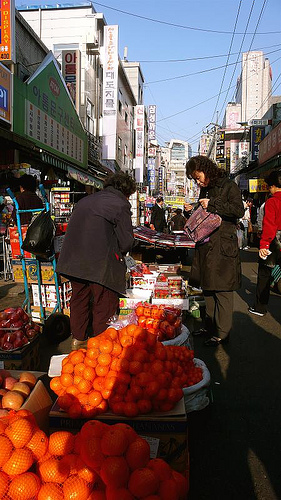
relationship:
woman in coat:
[173, 143, 247, 352] [182, 166, 251, 298]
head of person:
[97, 162, 150, 203] [52, 167, 144, 355]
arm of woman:
[44, 159, 144, 354] [53, 168, 139, 349]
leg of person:
[63, 269, 95, 344] [52, 167, 144, 355]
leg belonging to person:
[90, 282, 118, 336] [54, 170, 138, 350]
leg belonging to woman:
[211, 288, 235, 336] [184, 155, 246, 351]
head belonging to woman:
[185, 154, 213, 187] [184, 155, 246, 351]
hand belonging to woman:
[198, 197, 210, 208] [184, 155, 246, 351]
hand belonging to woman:
[181, 201, 192, 212] [184, 155, 246, 351]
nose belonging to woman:
[195, 178, 200, 184] [184, 155, 246, 351]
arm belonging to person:
[258, 199, 272, 248] [247, 169, 272, 315]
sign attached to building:
[11, 50, 89, 170] [12, 7, 92, 208]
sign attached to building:
[61, 48, 80, 118] [12, 7, 92, 208]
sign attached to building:
[100, 23, 117, 160] [17, 5, 145, 198]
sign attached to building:
[133, 104, 144, 183] [17, 5, 145, 198]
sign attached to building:
[237, 141, 249, 168] [229, 102, 272, 226]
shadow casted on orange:
[56, 305, 258, 499] [127, 359, 142, 374]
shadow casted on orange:
[56, 305, 258, 499] [154, 345, 167, 359]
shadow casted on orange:
[56, 305, 258, 499] [165, 385, 177, 401]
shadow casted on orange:
[56, 305, 258, 499] [122, 400, 137, 415]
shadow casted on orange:
[56, 305, 258, 499] [125, 435, 150, 469]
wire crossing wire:
[88, 0, 272, 35] [209, 0, 241, 124]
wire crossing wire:
[88, 0, 272, 35] [216, 1, 254, 123]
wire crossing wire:
[119, 41, 271, 64] [219, 1, 264, 126]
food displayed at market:
[1, 221, 202, 496] [1, 158, 279, 498]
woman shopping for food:
[184, 155, 246, 351] [1, 221, 202, 496]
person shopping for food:
[149, 195, 167, 231] [1, 221, 202, 496]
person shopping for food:
[169, 208, 186, 229] [1, 221, 202, 496]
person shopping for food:
[181, 198, 195, 217] [1, 221, 202, 496]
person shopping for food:
[242, 194, 253, 249] [1, 221, 202, 496]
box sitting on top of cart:
[7, 220, 68, 260] [4, 181, 75, 344]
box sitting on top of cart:
[10, 259, 71, 285] [4, 181, 75, 344]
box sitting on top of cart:
[29, 279, 73, 308] [4, 181, 75, 344]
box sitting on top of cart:
[30, 305, 70, 324] [4, 181, 75, 344]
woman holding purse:
[184, 155, 246, 351] [182, 205, 222, 243]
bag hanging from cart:
[18, 208, 53, 259] [4, 181, 75, 344]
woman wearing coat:
[53, 168, 139, 349] [54, 183, 136, 298]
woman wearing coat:
[184, 155, 246, 351] [187, 173, 245, 292]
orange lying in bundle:
[98, 427, 127, 456] [1, 408, 190, 498]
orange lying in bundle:
[127, 466, 159, 497] [1, 408, 190, 498]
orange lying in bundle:
[38, 459, 70, 484] [1, 408, 190, 498]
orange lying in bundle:
[3, 418, 35, 448] [1, 408, 190, 498]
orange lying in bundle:
[47, 430, 75, 455] [1, 408, 190, 498]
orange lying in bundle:
[119, 335, 133, 346] [48, 323, 204, 418]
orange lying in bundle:
[97, 352, 112, 364] [48, 323, 204, 418]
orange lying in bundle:
[134, 371, 149, 387] [48, 323, 204, 418]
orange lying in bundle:
[86, 388, 101, 406] [48, 323, 204, 418]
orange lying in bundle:
[86, 336, 100, 348] [48, 323, 204, 418]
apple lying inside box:
[16, 370, 35, 387] [0, 367, 56, 432]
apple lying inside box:
[10, 380, 30, 397] [0, 367, 56, 432]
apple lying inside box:
[1, 390, 23, 411] [0, 367, 56, 432]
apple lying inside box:
[2, 375, 17, 389] [0, 367, 56, 432]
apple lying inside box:
[1, 368, 12, 378] [0, 367, 56, 432]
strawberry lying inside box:
[154, 288, 158, 292] [151, 284, 190, 310]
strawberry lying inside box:
[157, 289, 162, 293] [151, 284, 190, 310]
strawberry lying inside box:
[155, 291, 163, 297] [151, 284, 190, 310]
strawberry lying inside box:
[171, 292, 175, 296] [151, 284, 190, 310]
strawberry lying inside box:
[162, 289, 167, 295] [151, 284, 190, 310]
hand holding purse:
[185, 203, 192, 214] [182, 205, 222, 243]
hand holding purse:
[199, 197, 210, 211] [182, 205, 222, 243]